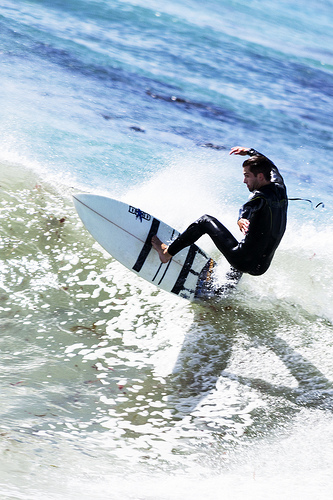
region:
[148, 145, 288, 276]
man wearing a black wet suit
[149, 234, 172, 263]
there are no shoes on the foot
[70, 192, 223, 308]
black and white surfboard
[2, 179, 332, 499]
white colored water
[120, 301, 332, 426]
shadows on the water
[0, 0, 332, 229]
blue colored water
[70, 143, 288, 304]
man on a surfboard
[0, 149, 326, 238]
water spraying around the surfer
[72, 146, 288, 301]
man falling on the surfboard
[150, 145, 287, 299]
man's arms are outstretched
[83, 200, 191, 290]
white surf board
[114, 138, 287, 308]
man surfing in ocean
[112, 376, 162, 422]
blue and white ocean waves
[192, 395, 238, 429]
blue and white ocean waves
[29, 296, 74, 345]
blue and white ocean waves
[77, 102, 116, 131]
blue and white ocean waves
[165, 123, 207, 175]
blue and white ocean waves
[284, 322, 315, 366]
blue and white ocean waves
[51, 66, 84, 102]
blue and white ocean waves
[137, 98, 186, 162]
blue and white ocean waves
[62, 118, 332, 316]
Young man surfing a wave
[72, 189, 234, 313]
white and black surfboard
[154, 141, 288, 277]
man wearing a long sleeved wet suit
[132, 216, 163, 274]
black stripe on the surfboard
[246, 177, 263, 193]
man with a brown beard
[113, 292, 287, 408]
white ocean foam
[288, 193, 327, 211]
black rip cord for the surfboard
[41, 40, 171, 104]
dark blue ocean water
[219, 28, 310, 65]
turquoise colored ocean water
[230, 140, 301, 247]
surfer with his right arm in the air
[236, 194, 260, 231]
the arm of a surfer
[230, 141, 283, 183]
the arm of a surfer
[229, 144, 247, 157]
the hand of a surfer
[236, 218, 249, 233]
the hand of surfer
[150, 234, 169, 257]
the foot of a surfer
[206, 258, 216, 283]
the white foot of a surfer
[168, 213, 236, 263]
the leg of a surfer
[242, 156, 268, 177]
brown hair on a head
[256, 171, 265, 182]
the ear of a surfer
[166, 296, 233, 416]
the shadow of a surfboard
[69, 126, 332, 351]
a man that is surfing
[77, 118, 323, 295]
a man on a surfboard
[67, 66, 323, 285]
a man riding a surfboard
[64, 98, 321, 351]
a surfer on a surfbaord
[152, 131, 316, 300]
a man wearing a wetsuit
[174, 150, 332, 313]
a man wearing a black wetsuti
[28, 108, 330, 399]
a body of water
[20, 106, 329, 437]
a body of water with waves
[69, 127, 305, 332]
a surfer wearing a wetsuit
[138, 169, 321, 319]
a surfer wearing a wetsuit